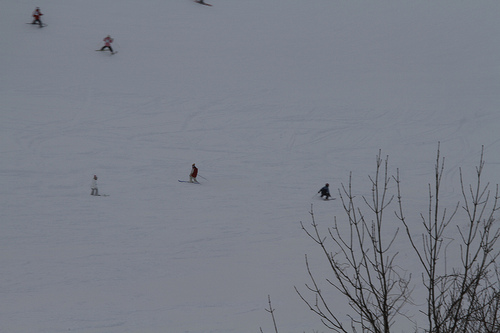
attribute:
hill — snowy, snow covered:
[0, 2, 499, 332]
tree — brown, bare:
[264, 141, 499, 332]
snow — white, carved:
[2, 2, 498, 332]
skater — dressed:
[87, 172, 114, 199]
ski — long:
[174, 174, 204, 189]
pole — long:
[314, 189, 322, 198]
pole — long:
[198, 171, 213, 187]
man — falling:
[190, 0, 217, 11]